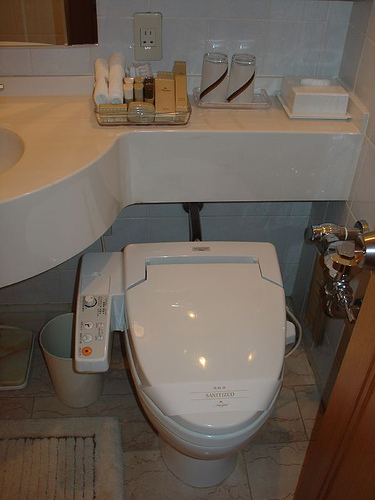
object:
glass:
[226, 53, 257, 103]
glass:
[199, 52, 228, 102]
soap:
[99, 103, 127, 123]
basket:
[92, 86, 192, 126]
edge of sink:
[0, 94, 121, 289]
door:
[64, 1, 99, 47]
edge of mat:
[0, 415, 125, 500]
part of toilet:
[75, 241, 297, 488]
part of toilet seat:
[125, 262, 286, 435]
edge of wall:
[0, 0, 375, 399]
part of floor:
[1, 297, 322, 500]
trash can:
[40, 312, 104, 408]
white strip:
[75, 252, 124, 374]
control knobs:
[85, 295, 98, 308]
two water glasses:
[199, 52, 256, 104]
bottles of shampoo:
[123, 83, 134, 104]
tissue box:
[280, 76, 350, 116]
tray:
[274, 89, 353, 120]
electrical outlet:
[133, 12, 163, 61]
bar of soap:
[128, 101, 156, 122]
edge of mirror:
[0, 1, 100, 47]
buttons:
[78, 294, 105, 356]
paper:
[141, 381, 282, 417]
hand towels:
[93, 54, 126, 106]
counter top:
[0, 75, 370, 290]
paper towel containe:
[154, 61, 188, 123]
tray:
[193, 87, 272, 110]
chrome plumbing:
[182, 202, 204, 243]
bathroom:
[0, 0, 375, 500]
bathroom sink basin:
[0, 124, 26, 179]